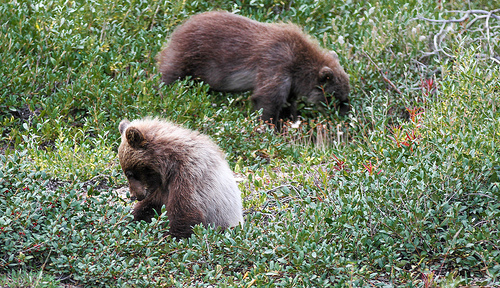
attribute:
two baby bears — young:
[115, 10, 352, 233]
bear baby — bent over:
[112, 116, 246, 236]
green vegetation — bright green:
[0, 1, 499, 286]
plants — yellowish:
[330, 200, 450, 259]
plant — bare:
[400, 3, 496, 66]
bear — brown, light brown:
[118, 117, 247, 235]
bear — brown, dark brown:
[158, 10, 352, 127]